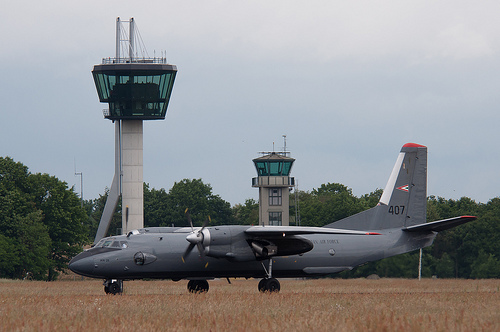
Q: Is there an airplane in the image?
A: Yes, there is an airplane.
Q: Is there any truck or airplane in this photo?
A: Yes, there is an airplane.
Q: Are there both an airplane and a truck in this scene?
A: No, there is an airplane but no trucks.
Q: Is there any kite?
A: No, there are no kites.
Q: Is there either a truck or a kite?
A: No, there are no kites or trucks.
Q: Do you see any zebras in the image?
A: No, there are no zebras.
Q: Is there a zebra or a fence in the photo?
A: No, there are no zebras or fences.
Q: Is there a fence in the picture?
A: No, there are no fences.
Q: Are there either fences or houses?
A: No, there are no fences or houses.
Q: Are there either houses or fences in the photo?
A: No, there are no fences or houses.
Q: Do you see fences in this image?
A: No, there are no fences.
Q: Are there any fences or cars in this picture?
A: No, there are no fences or cars.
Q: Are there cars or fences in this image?
A: No, there are no fences or cars.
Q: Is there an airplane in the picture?
A: Yes, there is an airplane.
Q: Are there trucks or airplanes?
A: Yes, there is an airplane.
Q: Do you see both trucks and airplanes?
A: No, there is an airplane but no trucks.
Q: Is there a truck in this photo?
A: No, there are no trucks.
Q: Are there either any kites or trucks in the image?
A: No, there are no trucks or kites.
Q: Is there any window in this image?
A: Yes, there are windows.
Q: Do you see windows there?
A: Yes, there are windows.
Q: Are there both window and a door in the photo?
A: No, there are windows but no doors.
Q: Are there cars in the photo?
A: No, there are no cars.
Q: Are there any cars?
A: No, there are no cars.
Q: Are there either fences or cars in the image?
A: No, there are no cars or fences.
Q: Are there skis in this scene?
A: No, there are no skis.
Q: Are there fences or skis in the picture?
A: No, there are no skis or fences.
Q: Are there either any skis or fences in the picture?
A: No, there are no skis or fences.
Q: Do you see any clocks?
A: No, there are no clocks.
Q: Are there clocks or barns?
A: No, there are no clocks or barns.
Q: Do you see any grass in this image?
A: Yes, there is grass.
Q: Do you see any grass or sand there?
A: Yes, there is grass.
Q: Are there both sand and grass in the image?
A: No, there is grass but no sand.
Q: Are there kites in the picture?
A: No, there are no kites.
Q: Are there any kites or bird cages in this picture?
A: No, there are no kites or bird cages.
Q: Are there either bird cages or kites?
A: No, there are no kites or bird cages.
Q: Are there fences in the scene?
A: No, there are no fences.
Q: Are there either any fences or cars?
A: No, there are no fences or cars.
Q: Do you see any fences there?
A: No, there are no fences.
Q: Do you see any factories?
A: No, there are no factories.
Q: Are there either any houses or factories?
A: No, there are no factories or houses.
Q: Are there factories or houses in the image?
A: No, there are no factories or houses.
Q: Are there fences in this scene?
A: No, there are no fences.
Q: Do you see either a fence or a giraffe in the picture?
A: No, there are no fences or giraffes.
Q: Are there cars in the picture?
A: No, there are no cars.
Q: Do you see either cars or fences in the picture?
A: No, there are no cars or fences.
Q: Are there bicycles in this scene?
A: No, there are no bicycles.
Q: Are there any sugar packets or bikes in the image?
A: No, there are no bikes or sugar packets.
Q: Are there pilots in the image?
A: No, there are no pilots.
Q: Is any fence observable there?
A: No, there are no fences.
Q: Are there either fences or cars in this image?
A: No, there are no fences or cars.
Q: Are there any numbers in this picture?
A: Yes, there are numbers.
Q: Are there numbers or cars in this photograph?
A: Yes, there are numbers.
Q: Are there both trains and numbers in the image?
A: No, there are numbers but no trains.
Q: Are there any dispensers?
A: No, there are no dispensers.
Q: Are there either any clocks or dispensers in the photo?
A: No, there are no dispensers or clocks.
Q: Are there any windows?
A: Yes, there are windows.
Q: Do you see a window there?
A: Yes, there are windows.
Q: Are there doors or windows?
A: Yes, there are windows.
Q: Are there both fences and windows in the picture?
A: No, there are windows but no fences.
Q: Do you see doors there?
A: No, there are no doors.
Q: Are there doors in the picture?
A: No, there are no doors.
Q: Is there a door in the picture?
A: No, there are no doors.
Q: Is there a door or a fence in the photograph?
A: No, there are no doors or fences.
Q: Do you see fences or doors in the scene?
A: No, there are no doors or fences.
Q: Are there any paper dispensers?
A: No, there are no paper dispensers.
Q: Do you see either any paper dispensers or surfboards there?
A: No, there are no paper dispensers or surfboards.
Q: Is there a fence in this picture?
A: No, there are no fences.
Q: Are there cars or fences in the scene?
A: No, there are no fences or cars.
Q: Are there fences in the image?
A: No, there are no fences.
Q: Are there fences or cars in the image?
A: No, there are no fences or cars.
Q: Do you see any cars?
A: No, there are no cars.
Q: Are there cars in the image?
A: No, there are no cars.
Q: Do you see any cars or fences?
A: No, there are no cars or fences.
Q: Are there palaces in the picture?
A: No, there are no palaces.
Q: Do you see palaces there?
A: No, there are no palaces.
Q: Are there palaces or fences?
A: No, there are no palaces or fences.